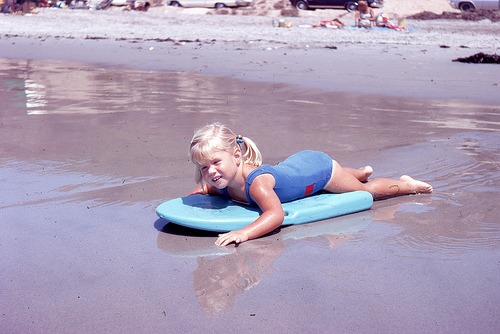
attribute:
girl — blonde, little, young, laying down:
[183, 121, 436, 249]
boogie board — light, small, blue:
[152, 183, 377, 237]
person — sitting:
[353, 0, 375, 30]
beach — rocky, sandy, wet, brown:
[1, 6, 498, 94]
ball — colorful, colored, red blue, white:
[373, 11, 388, 25]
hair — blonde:
[182, 117, 267, 195]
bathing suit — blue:
[214, 147, 335, 207]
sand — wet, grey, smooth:
[5, 32, 499, 101]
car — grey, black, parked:
[290, 0, 385, 15]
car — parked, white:
[155, 1, 249, 13]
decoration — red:
[301, 182, 315, 198]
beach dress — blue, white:
[355, 8, 372, 26]